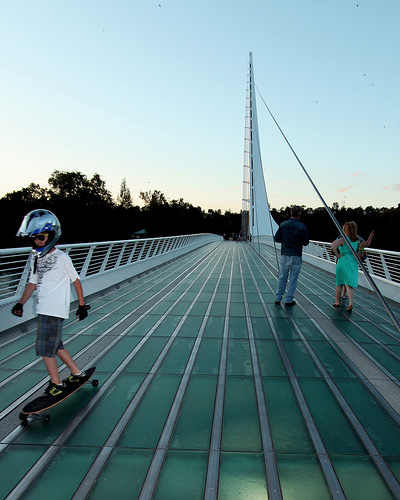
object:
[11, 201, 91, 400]
boy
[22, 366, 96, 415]
skateboard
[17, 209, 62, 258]
helmet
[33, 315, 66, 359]
shorts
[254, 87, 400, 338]
suspension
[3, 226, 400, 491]
bridge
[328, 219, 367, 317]
woman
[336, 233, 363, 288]
dress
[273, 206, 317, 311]
man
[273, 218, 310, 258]
shirt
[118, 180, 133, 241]
trees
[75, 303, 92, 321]
gloves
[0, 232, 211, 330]
railing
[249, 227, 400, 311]
railing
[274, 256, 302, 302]
jeans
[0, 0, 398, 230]
sky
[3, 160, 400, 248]
landscape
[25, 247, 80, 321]
t-shirt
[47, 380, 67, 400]
sneaker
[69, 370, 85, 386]
sneaker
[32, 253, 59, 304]
design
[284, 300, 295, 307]
shoes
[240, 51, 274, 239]
structure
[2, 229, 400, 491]
pathway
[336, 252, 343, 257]
hand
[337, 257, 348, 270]
hip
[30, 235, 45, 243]
suglasses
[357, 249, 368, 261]
purse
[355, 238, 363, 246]
shoulder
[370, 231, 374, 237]
hand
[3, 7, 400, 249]
distance